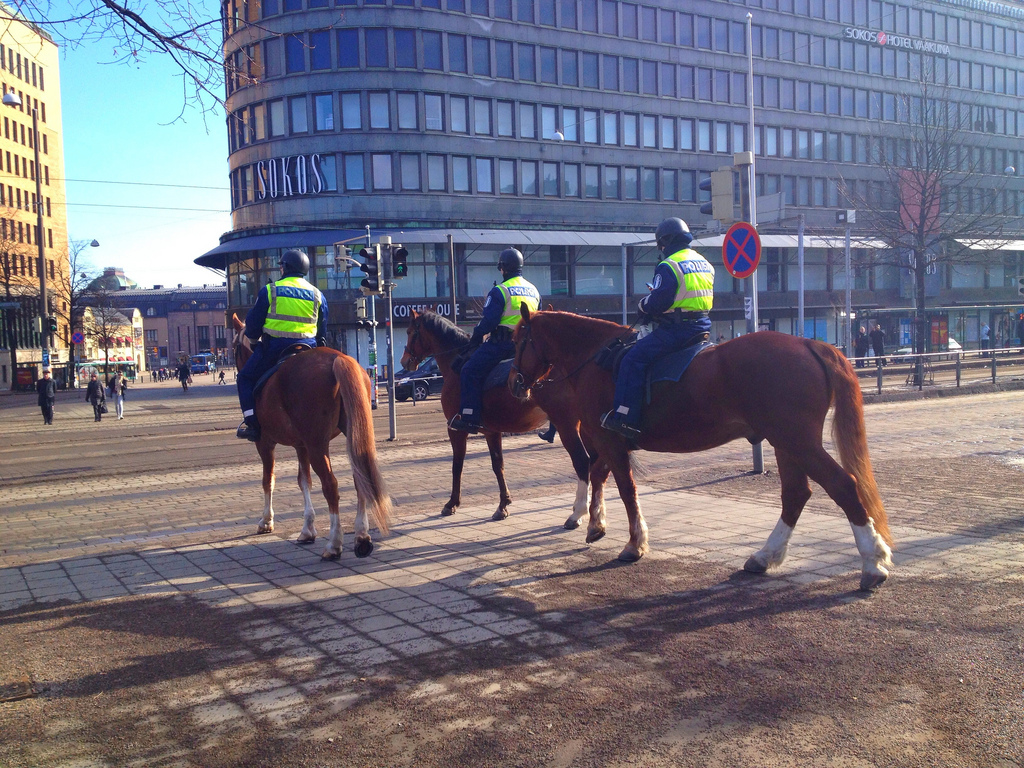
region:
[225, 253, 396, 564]
man riding a horse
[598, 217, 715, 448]
man wearing a black helmet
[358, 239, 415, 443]
traffic light on the street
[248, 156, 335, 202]
business name on building wall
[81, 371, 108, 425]
person carrying a briefcase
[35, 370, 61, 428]
man crossing the street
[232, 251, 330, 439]
man wearing a police vest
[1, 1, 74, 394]
beige building in the distance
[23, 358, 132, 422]
people on the far side of the street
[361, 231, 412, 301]
traffic signal on the side of the street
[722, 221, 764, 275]
blue and red sign on a pole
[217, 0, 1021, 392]
large building with a curved corner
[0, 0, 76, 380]
brown stone building in the distance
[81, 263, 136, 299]
domed roof past the brown building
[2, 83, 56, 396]
street light on the far side of the street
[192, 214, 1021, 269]
awning wrapped around curved building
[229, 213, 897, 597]
three mounted police on brown horses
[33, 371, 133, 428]
three people walking along a street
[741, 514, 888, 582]
white area above hooves on a horse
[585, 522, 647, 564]
front hooves of a horse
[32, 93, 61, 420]
black metal pole on a street corner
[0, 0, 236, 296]
blue sky with some clouds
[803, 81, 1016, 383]
bare tree next to a city street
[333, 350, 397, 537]
reddish brown tail of a horse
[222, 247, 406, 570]
Police man on a horse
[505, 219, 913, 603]
Police man on a horse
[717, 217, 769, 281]
Railroad crossing sign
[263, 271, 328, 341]
Safety vest of the police man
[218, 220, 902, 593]
Three policemen on horses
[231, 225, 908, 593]
Policemen on brown horses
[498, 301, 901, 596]
Brown horse walking on the street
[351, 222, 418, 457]
A traffic light on a pole.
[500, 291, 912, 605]
A brown horse with white hooves.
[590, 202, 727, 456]
A police officer riding a horse.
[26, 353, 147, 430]
People standing along a street.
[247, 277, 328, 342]
A yellow colored safety vest.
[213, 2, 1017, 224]
Many windows in a building.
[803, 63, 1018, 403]
A tree with no leaves.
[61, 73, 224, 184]
A blue colored sky.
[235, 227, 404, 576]
police officer riding brown horse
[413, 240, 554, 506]
police officer riding brown horse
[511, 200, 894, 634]
police officer riding brown horse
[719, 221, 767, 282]
red and blue sign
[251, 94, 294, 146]
window in brown building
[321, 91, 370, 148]
window in brown building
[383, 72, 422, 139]
window in brown building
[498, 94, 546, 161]
window in brown building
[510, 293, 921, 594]
brown horse ridden by law enforcement officer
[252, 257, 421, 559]
brown horse ridden by law enforcement officer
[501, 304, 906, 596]
a large brown and white horse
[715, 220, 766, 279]
a red and blue sign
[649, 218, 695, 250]
a black helmet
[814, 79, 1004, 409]
a tree with no leaves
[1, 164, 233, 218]
electrical power lines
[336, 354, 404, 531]
a long horse tail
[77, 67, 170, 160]
a blue sky